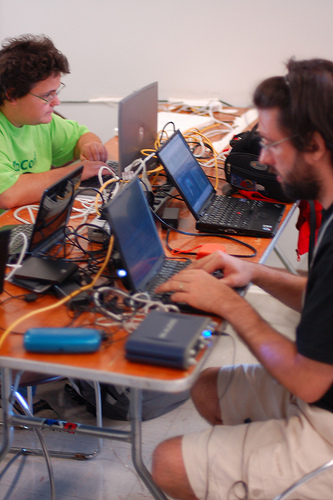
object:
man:
[152, 58, 333, 500]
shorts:
[181, 357, 333, 500]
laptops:
[6, 79, 283, 316]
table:
[1, 105, 300, 395]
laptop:
[155, 127, 291, 236]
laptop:
[80, 81, 159, 185]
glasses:
[256, 131, 307, 152]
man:
[0, 29, 108, 212]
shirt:
[0, 114, 91, 195]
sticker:
[40, 417, 83, 433]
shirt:
[290, 202, 332, 412]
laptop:
[107, 175, 219, 312]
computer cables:
[0, 98, 242, 333]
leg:
[0, 368, 145, 497]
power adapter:
[160, 196, 181, 234]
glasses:
[30, 79, 69, 101]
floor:
[75, 465, 100, 500]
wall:
[0, 3, 333, 106]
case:
[25, 326, 102, 355]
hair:
[1, 30, 72, 103]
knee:
[190, 363, 213, 420]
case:
[16, 250, 81, 291]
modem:
[223, 134, 299, 194]